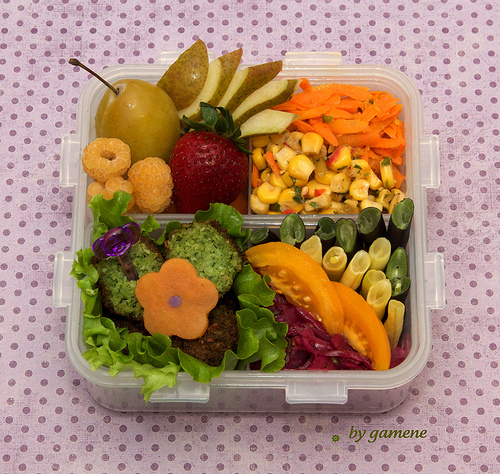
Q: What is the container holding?
A: Food.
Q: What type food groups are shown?
A: Vegetable and fruits.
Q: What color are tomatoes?
A: Orange.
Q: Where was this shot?
A: Table.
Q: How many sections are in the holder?
A: 3.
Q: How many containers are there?
A: 1.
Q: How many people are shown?
A: 0.